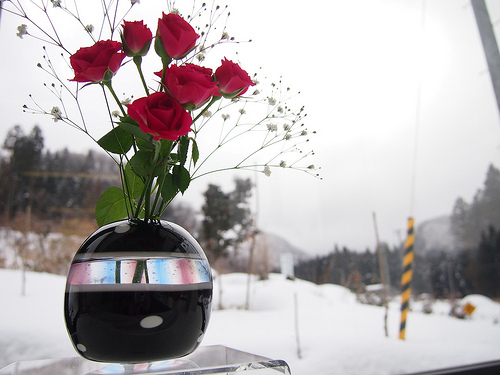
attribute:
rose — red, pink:
[67, 35, 112, 83]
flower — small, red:
[71, 44, 146, 184]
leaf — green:
[98, 121, 138, 154]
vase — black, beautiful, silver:
[72, 210, 199, 350]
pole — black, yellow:
[385, 200, 429, 339]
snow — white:
[317, 298, 367, 358]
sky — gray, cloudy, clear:
[343, 13, 422, 130]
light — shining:
[100, 228, 129, 252]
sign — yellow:
[462, 294, 480, 317]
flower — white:
[247, 117, 290, 149]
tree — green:
[459, 238, 498, 281]